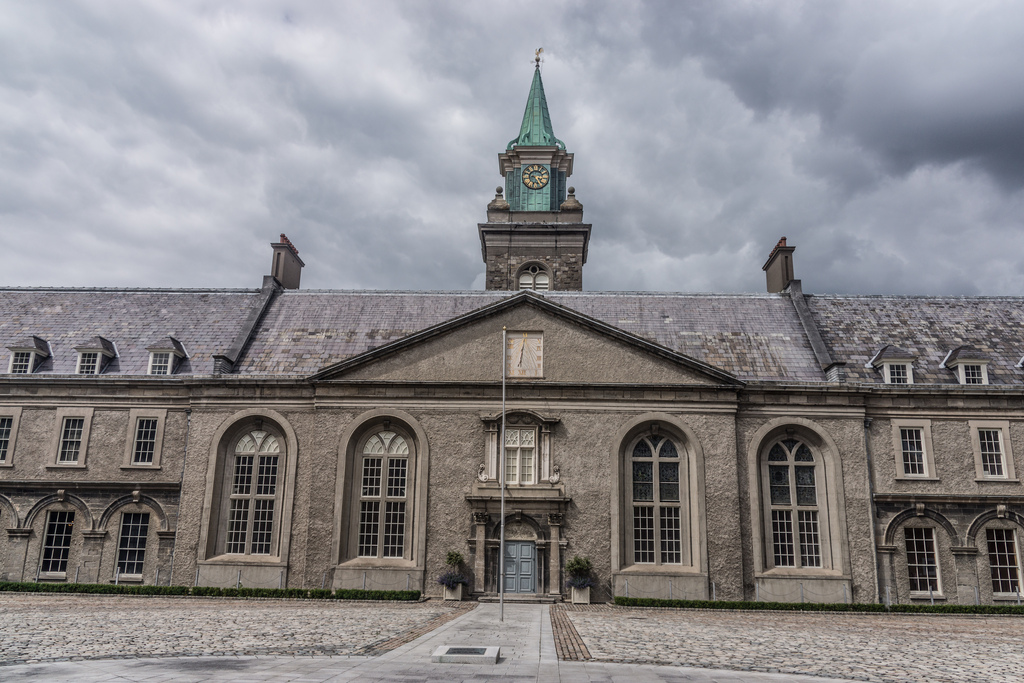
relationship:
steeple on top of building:
[453, 45, 600, 303] [0, 33, 1022, 610]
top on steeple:
[501, 25, 590, 159] [466, 36, 614, 305]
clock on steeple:
[509, 155, 562, 197] [470, 47, 600, 294]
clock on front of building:
[492, 325, 590, 395] [10, 56, 1020, 642]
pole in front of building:
[470, 306, 546, 650] [10, 56, 1020, 642]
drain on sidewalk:
[421, 634, 517, 676] [6, 581, 1022, 677]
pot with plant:
[438, 580, 478, 607] [432, 535, 489, 607]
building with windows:
[0, 33, 1022, 610] [17, 406, 1022, 605]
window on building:
[611, 412, 709, 578] [0, 33, 1022, 610]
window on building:
[761, 434, 833, 571] [10, 56, 1020, 642]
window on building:
[900, 426, 932, 477] [0, 33, 1022, 610]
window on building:
[978, 429, 1010, 479] [0, 33, 1022, 610]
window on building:
[986, 529, 1021, 593] [0, 33, 1022, 610]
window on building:
[347, 423, 416, 560] [0, 33, 1022, 610]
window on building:
[216, 421, 288, 555] [0, 33, 1022, 610]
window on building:
[131, 418, 158, 466] [0, 33, 1022, 610]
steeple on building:
[477, 47, 592, 291] [0, 33, 1022, 610]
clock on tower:
[521, 164, 548, 190] [474, 46, 598, 288]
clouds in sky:
[16, 9, 1010, 303] [0, 0, 1012, 301]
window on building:
[761, 434, 833, 571] [0, 33, 1022, 610]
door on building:
[485, 504, 542, 604] [0, 33, 1022, 610]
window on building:
[55, 416, 85, 466] [0, 33, 1022, 610]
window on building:
[41, 510, 76, 573] [0, 33, 1022, 610]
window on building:
[105, 506, 162, 576] [0, 33, 1022, 610]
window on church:
[986, 529, 1021, 593] [0, 35, 1024, 610]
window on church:
[904, 526, 943, 596] [0, 35, 1024, 610]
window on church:
[978, 429, 1010, 479] [0, 35, 1024, 610]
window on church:
[900, 426, 932, 477] [0, 35, 1024, 610]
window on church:
[761, 434, 833, 571] [0, 35, 1024, 610]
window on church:
[977, 519, 1021, 593] [0, 35, 1024, 610]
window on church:
[974, 426, 1007, 479] [0, 35, 1024, 610]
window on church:
[896, 424, 927, 476] [0, 35, 1024, 610]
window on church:
[760, 424, 827, 565] [0, 35, 1024, 610]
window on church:
[972, 420, 1007, 475] [0, 35, 1024, 610]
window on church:
[896, 525, 946, 597] [0, 35, 1024, 610]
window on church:
[611, 412, 709, 578] [0, 35, 1024, 610]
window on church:
[131, 418, 158, 466] [0, 35, 1024, 610]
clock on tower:
[521, 164, 548, 190] [477, 39, 592, 292]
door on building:
[468, 509, 569, 604] [0, 33, 1022, 610]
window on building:
[52, 407, 81, 462] [0, 33, 1022, 610]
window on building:
[127, 413, 164, 468] [0, 33, 1022, 610]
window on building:
[112, 512, 151, 579] [0, 33, 1022, 610]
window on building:
[35, 504, 75, 574] [0, 33, 1022, 610]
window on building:
[6, 351, 34, 374] [0, 33, 1022, 610]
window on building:
[76, 351, 104, 375] [0, 33, 1022, 610]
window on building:
[147, 352, 175, 375] [0, 33, 1022, 610]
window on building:
[863, 346, 915, 385] [0, 33, 1022, 610]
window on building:
[958, 363, 990, 385] [0, 33, 1022, 610]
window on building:
[950, 357, 994, 390] [0, 33, 1022, 610]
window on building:
[149, 342, 175, 386] [0, 33, 1022, 610]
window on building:
[76, 342, 102, 386] [0, 33, 1022, 610]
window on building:
[7, 346, 34, 373] [0, 33, 1022, 610]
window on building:
[348, 415, 409, 563] [0, 33, 1022, 610]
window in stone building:
[197, 418, 297, 555] [37, 347, 986, 683]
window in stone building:
[761, 434, 833, 571] [78, 338, 900, 683]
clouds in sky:
[0, 0, 1024, 298] [292, 254, 476, 274]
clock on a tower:
[521, 164, 548, 190] [447, 207, 633, 395]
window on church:
[611, 412, 709, 578] [45, 104, 992, 619]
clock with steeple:
[521, 164, 548, 190] [467, 74, 666, 379]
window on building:
[610, 408, 710, 583] [0, 33, 1022, 610]